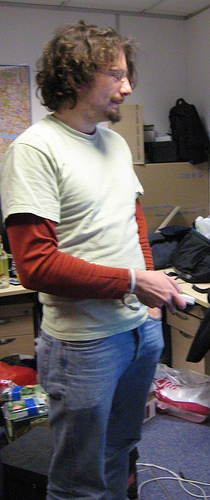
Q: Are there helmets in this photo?
A: No, there are no helmets.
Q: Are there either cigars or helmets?
A: No, there are no helmets or cigars.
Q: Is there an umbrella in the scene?
A: No, there are no umbrellas.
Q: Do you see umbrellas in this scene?
A: No, there are no umbrellas.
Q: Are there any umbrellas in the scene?
A: No, there are no umbrellas.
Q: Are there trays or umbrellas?
A: No, there are no umbrellas or trays.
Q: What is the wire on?
A: The wire is on the carpet.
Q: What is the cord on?
A: The wire is on the carpet.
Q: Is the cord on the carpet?
A: Yes, the cord is on the carpet.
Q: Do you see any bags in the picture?
A: Yes, there is a bag.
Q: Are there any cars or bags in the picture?
A: Yes, there is a bag.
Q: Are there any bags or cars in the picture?
A: Yes, there is a bag.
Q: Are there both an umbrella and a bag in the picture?
A: No, there is a bag but no umbrellas.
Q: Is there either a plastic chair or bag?
A: Yes, there is a plastic bag.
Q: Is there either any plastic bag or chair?
A: Yes, there is a plastic bag.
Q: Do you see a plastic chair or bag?
A: Yes, there is a plastic bag.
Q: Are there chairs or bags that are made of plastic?
A: Yes, the bag is made of plastic.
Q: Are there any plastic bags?
A: Yes, there is a bag that is made of plastic.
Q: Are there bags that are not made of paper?
A: Yes, there is a bag that is made of plastic.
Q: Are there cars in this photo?
A: No, there are no cars.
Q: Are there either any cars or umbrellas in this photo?
A: No, there are no cars or umbrellas.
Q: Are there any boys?
A: No, there are no boys.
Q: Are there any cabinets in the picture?
A: Yes, there is a cabinet.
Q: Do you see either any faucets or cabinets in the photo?
A: Yes, there is a cabinet.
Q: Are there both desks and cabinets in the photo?
A: Yes, there are both a cabinet and a desk.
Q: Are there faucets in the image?
A: No, there are no faucets.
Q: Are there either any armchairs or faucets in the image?
A: No, there are no faucets or armchairs.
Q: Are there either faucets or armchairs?
A: No, there are no faucets or armchairs.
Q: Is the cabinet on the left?
A: Yes, the cabinet is on the left of the image.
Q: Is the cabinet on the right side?
A: No, the cabinet is on the left of the image.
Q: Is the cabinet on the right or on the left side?
A: The cabinet is on the left of the image.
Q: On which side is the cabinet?
A: The cabinet is on the left of the image.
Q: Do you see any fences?
A: No, there are no fences.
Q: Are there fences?
A: No, there are no fences.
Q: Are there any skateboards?
A: No, there are no skateboards.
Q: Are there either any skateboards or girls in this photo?
A: No, there are no skateboards or girls.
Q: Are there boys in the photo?
A: No, there are no boys.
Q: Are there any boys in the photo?
A: No, there are no boys.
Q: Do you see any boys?
A: No, there are no boys.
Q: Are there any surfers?
A: No, there are no surfers.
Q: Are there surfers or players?
A: No, there are no surfers or players.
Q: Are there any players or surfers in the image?
A: No, there are no surfers or players.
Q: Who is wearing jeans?
A: The man is wearing jeans.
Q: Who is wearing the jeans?
A: The man is wearing jeans.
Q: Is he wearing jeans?
A: Yes, the man is wearing jeans.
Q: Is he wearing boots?
A: No, the man is wearing jeans.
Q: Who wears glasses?
A: The man wears glasses.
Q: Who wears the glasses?
A: The man wears glasses.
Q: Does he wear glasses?
A: Yes, the man wears glasses.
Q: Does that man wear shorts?
A: No, the man wears glasses.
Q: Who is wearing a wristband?
A: The man is wearing a wristband.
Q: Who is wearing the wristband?
A: The man is wearing a wristband.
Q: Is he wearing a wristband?
A: Yes, the man is wearing a wristband.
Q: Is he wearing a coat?
A: No, the man is wearing a wristband.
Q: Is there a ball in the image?
A: No, there are no balls.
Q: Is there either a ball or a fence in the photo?
A: No, there are no balls or fences.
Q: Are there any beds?
A: No, there are no beds.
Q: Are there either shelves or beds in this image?
A: No, there are no beds or shelves.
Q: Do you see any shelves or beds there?
A: No, there are no beds or shelves.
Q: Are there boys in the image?
A: No, there are no boys.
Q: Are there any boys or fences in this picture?
A: No, there are no boys or fences.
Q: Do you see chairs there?
A: No, there are no chairs.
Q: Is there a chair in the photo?
A: No, there are no chairs.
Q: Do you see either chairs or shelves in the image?
A: No, there are no chairs or shelves.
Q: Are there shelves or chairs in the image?
A: No, there are no chairs or shelves.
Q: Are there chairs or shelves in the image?
A: No, there are no chairs or shelves.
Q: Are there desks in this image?
A: Yes, there is a desk.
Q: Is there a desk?
A: Yes, there is a desk.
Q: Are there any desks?
A: Yes, there is a desk.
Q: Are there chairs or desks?
A: Yes, there is a desk.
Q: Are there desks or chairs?
A: Yes, there is a desk.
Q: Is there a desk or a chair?
A: Yes, there is a desk.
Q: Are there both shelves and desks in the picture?
A: No, there is a desk but no shelves.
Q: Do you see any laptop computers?
A: No, there are no laptop computers.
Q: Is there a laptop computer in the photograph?
A: No, there are no laptops.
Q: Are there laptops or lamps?
A: No, there are no laptops or lamps.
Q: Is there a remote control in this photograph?
A: Yes, there is a remote control.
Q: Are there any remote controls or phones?
A: Yes, there is a remote control.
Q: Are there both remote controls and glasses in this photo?
A: Yes, there are both a remote control and glasses.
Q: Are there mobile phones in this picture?
A: No, there are no mobile phones.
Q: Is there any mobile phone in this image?
A: No, there are no cell phones.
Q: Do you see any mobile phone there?
A: No, there are no cell phones.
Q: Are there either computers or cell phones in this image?
A: No, there are no cell phones or computers.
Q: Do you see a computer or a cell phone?
A: No, there are no cell phones or computers.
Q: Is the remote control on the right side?
A: Yes, the remote control is on the right of the image.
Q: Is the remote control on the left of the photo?
A: No, the remote control is on the right of the image.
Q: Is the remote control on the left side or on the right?
A: The remote control is on the right of the image.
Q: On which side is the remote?
A: The remote is on the right of the image.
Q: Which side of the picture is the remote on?
A: The remote is on the right of the image.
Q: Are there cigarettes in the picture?
A: No, there are no cigarettes.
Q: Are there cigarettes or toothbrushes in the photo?
A: No, there are no cigarettes or toothbrushes.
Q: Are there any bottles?
A: Yes, there is a bottle.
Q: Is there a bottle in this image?
A: Yes, there is a bottle.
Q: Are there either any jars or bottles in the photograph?
A: Yes, there is a bottle.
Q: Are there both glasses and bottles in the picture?
A: Yes, there are both a bottle and glasses.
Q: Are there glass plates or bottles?
A: Yes, there is a glass bottle.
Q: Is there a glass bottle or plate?
A: Yes, there is a glass bottle.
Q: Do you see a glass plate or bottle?
A: Yes, there is a glass bottle.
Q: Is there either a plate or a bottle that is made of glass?
A: Yes, the bottle is made of glass.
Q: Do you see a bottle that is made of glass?
A: Yes, there is a bottle that is made of glass.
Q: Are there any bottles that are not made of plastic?
A: Yes, there is a bottle that is made of glass.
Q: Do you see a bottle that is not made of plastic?
A: Yes, there is a bottle that is made of glass.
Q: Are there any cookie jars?
A: No, there are no cookie jars.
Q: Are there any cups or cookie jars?
A: No, there are no cookie jars or cups.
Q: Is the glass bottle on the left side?
A: Yes, the bottle is on the left of the image.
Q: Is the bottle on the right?
A: No, the bottle is on the left of the image.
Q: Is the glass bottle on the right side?
A: No, the bottle is on the left of the image.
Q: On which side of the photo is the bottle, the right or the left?
A: The bottle is on the left of the image.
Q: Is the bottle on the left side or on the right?
A: The bottle is on the left of the image.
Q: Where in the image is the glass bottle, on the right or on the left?
A: The bottle is on the left of the image.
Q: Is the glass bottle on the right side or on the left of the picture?
A: The bottle is on the left of the image.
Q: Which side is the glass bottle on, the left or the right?
A: The bottle is on the left of the image.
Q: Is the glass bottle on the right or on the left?
A: The bottle is on the left of the image.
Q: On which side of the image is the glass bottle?
A: The bottle is on the left of the image.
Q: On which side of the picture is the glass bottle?
A: The bottle is on the left of the image.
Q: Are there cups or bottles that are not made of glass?
A: No, there is a bottle but it is made of glass.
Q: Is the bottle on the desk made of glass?
A: Yes, the bottle is made of glass.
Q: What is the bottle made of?
A: The bottle is made of glass.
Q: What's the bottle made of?
A: The bottle is made of glass.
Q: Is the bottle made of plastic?
A: No, the bottle is made of glass.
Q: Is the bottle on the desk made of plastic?
A: No, the bottle is made of glass.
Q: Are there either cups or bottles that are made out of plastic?
A: No, there is a bottle but it is made of glass.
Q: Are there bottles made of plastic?
A: No, there is a bottle but it is made of glass.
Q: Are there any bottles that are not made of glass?
A: No, there is a bottle but it is made of glass.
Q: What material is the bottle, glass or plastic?
A: The bottle is made of glass.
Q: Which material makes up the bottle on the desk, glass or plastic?
A: The bottle is made of glass.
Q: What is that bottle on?
A: The bottle is on the desk.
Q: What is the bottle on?
A: The bottle is on the desk.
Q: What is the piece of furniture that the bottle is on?
A: The piece of furniture is a desk.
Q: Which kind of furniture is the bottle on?
A: The bottle is on the desk.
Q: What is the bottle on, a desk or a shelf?
A: The bottle is on a desk.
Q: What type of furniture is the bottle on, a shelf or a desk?
A: The bottle is on a desk.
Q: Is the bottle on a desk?
A: Yes, the bottle is on a desk.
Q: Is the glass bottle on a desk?
A: Yes, the bottle is on a desk.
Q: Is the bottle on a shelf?
A: No, the bottle is on a desk.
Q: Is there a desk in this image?
A: Yes, there is a desk.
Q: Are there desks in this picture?
A: Yes, there is a desk.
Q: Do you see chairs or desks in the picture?
A: Yes, there is a desk.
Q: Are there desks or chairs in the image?
A: Yes, there is a desk.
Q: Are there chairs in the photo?
A: No, there are no chairs.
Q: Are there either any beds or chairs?
A: No, there are no chairs or beds.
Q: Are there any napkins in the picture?
A: No, there are no napkins.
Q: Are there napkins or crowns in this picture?
A: No, there are no napkins or crowns.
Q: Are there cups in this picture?
A: No, there are no cups.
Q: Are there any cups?
A: No, there are no cups.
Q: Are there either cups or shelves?
A: No, there are no cups or shelves.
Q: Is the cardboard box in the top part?
A: Yes, the box is in the top of the image.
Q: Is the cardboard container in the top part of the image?
A: Yes, the box is in the top of the image.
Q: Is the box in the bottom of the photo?
A: No, the box is in the top of the image.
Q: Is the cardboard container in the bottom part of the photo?
A: No, the box is in the top of the image.